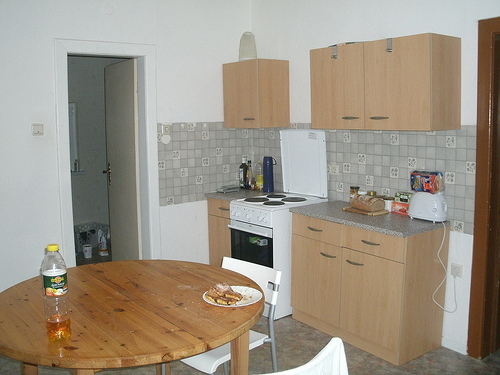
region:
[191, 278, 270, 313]
a plate with food on it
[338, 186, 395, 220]
bread on a cutting board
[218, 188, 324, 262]
an oven with cook top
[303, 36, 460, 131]
kitchen cubards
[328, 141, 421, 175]
a tiled back splash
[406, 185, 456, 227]
a white toaster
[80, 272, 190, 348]
a wooden table top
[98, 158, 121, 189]
a doorknob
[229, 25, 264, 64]
a glass vase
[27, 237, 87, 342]
a nearly empty bottle of yellowish liquid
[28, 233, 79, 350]
a bottle of apple juice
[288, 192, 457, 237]
a gray kitchen counter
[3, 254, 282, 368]
a wooden kitchen table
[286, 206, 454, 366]
a set of kitchen cabinets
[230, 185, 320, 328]
a white electric stove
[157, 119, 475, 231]
a grey tile backsplash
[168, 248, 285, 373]
a white dining room chair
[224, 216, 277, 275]
a black oven door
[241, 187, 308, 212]
four stove burners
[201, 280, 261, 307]
a plate of food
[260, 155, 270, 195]
a blue thermos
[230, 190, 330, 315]
a white kitchen stove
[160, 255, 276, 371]
a white kitchen chair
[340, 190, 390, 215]
a loaf of bread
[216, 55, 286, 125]
a kitchen wall cabinet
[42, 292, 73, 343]
a glass on the table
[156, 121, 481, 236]
tiles on a kitchen wall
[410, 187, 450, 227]
white toaster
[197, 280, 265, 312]
half eaten meal on white plate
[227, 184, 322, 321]
white oven with range-top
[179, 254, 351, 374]
two white kitchen chairs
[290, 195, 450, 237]
gray granite countertop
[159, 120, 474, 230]
wall tile decoration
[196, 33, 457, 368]
light brown kitchen cabinets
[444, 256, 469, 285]
electrical wall outlet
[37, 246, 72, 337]
almost empty bottle of juice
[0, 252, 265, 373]
a brown, wooden kitchen table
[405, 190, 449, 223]
White toaster on the countertop.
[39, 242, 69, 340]
Nearly empty bottle of Pine-Sol on the table.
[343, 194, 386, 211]
Loaf of bread on cutting board.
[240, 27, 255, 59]
Plastic container on tops of cabinets.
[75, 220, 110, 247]
Laundry basket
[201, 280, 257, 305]
a plate of food on the table.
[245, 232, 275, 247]
a box in the oven.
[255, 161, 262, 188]
a bottle of cooking oil.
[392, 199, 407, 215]
a box of teabags.